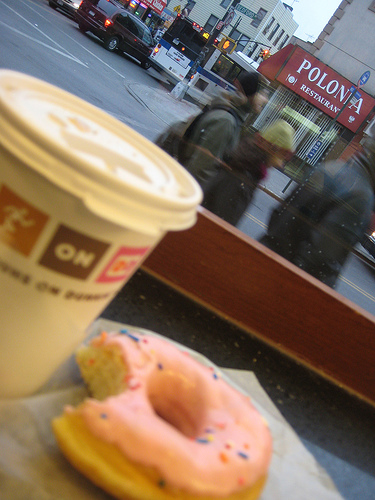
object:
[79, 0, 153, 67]
minivan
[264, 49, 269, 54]
light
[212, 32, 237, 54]
sign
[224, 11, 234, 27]
sign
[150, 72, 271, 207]
person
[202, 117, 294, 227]
person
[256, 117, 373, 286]
person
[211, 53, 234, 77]
window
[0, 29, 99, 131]
ground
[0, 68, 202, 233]
lid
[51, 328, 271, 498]
coffee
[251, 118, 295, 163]
cap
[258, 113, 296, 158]
head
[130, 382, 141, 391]
pink icing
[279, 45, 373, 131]
sign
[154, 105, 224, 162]
backpack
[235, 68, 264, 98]
cap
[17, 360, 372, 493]
table top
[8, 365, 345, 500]
paper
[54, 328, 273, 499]
donut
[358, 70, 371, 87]
sign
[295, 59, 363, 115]
polonia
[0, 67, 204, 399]
coffee cup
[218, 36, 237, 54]
crosswalk sign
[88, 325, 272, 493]
icing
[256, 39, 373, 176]
store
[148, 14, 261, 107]
bus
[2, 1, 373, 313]
street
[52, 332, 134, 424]
bite